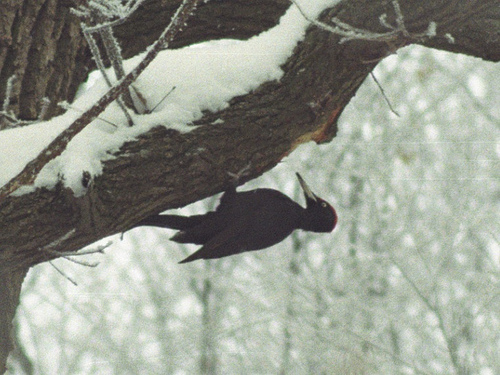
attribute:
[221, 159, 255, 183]
foot — bird's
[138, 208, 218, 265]
tail feathers — tall, black, bird's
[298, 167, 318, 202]
beak — pointed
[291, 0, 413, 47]
twigs — frosted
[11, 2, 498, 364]
trees — snowy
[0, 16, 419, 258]
branch — covered, snowy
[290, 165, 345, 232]
beak — long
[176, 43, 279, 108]
snow — white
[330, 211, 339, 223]
patch — RED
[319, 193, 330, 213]
eye — yellow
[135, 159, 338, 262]
bird — black